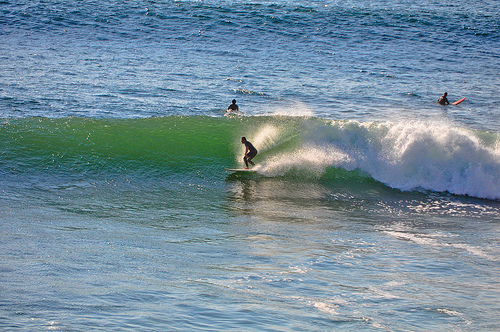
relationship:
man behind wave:
[227, 99, 238, 112] [2, 112, 497, 201]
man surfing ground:
[227, 99, 238, 112] [0, 0, 500, 332]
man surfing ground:
[437, 92, 450, 106] [0, 0, 500, 332]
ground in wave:
[0, 0, 500, 332] [1, 105, 496, 208]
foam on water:
[309, 299, 338, 318] [55, 159, 158, 229]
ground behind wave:
[0, 0, 500, 332] [2, 112, 497, 201]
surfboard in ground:
[226, 164, 260, 177] [0, 0, 500, 332]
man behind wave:
[227, 99, 238, 112] [74, 112, 349, 139]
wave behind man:
[223, 85, 269, 96] [227, 98, 241, 112]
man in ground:
[225, 97, 241, 112] [0, 0, 500, 332]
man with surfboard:
[437, 92, 448, 109] [448, 96, 465, 106]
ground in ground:
[0, 0, 500, 332] [0, 0, 500, 332]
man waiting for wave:
[437, 92, 450, 106] [13, 109, 499, 195]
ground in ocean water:
[0, 0, 500, 332] [4, 2, 484, 321]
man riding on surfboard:
[227, 99, 238, 112] [448, 92, 469, 109]